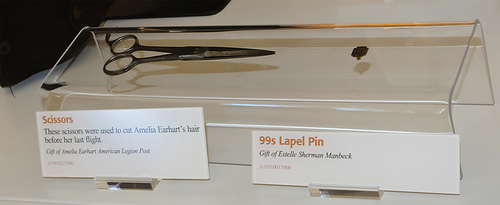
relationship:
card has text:
[35, 106, 209, 179] [43, 115, 73, 123]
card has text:
[252, 131, 461, 195] [280, 135, 305, 146]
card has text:
[35, 106, 209, 179] [43, 127, 61, 134]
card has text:
[252, 131, 461, 195] [259, 150, 271, 158]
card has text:
[35, 106, 209, 179] [139, 148, 150, 154]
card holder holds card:
[94, 176, 162, 190] [35, 106, 209, 179]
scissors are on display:
[103, 30, 276, 76] [39, 19, 496, 179]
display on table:
[39, 19, 496, 179] [0, 0, 500, 205]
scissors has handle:
[103, 30, 276, 76] [105, 33, 139, 55]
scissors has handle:
[103, 30, 276, 76] [103, 52, 137, 75]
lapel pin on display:
[351, 46, 369, 60] [39, 19, 496, 179]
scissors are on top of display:
[103, 30, 276, 76] [39, 19, 496, 179]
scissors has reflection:
[103, 30, 276, 76] [107, 50, 280, 93]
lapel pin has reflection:
[351, 46, 369, 60] [354, 61, 372, 74]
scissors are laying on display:
[103, 30, 276, 76] [39, 19, 496, 179]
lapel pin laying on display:
[351, 46, 369, 60] [39, 19, 496, 179]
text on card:
[43, 115, 73, 123] [35, 106, 209, 179]